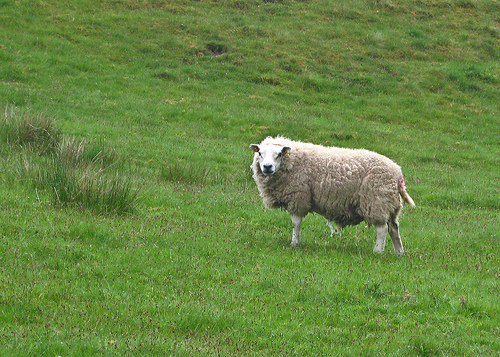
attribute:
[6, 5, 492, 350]
field — open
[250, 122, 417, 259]
whitesheep — white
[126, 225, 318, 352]
grass — green 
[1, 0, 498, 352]
grass — green 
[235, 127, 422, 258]
ram — standing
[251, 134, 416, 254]
ram — wooly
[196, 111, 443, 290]
sheep — white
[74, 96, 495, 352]
field — open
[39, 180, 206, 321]
grass — longer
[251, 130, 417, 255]
sheep — white 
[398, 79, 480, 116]
grass — green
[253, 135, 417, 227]
wool — grey 